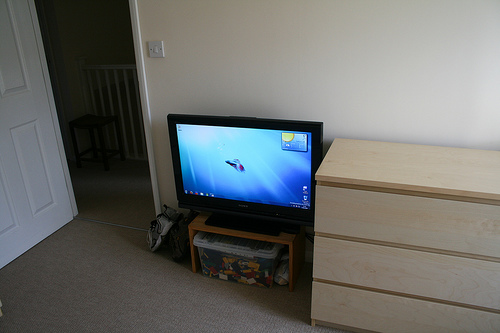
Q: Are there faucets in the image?
A: No, there are no faucets.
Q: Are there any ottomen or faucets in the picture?
A: No, there are no faucets or ottomen.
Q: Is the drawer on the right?
A: Yes, the drawer is on the right of the image.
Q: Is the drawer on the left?
A: No, the drawer is on the right of the image.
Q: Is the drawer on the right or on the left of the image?
A: The drawer is on the right of the image.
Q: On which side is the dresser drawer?
A: The drawer is on the right of the image.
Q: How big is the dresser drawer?
A: The drawer is large.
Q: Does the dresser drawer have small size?
A: No, the drawer is large.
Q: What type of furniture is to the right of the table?
A: The piece of furniture is a drawer.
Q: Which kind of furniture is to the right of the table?
A: The piece of furniture is a drawer.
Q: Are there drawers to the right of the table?
A: Yes, there is a drawer to the right of the table.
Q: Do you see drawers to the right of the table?
A: Yes, there is a drawer to the right of the table.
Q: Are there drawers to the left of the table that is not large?
A: No, the drawer is to the right of the table.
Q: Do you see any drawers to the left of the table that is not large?
A: No, the drawer is to the right of the table.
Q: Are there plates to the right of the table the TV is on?
A: No, there is a drawer to the right of the table.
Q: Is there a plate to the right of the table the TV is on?
A: No, there is a drawer to the right of the table.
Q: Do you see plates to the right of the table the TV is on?
A: No, there is a drawer to the right of the table.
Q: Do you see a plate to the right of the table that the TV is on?
A: No, there is a drawer to the right of the table.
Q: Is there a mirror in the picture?
A: No, there are no mirrors.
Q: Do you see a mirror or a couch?
A: No, there are no mirrors or couches.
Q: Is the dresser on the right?
A: Yes, the dresser is on the right of the image.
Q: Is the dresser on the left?
A: No, the dresser is on the right of the image.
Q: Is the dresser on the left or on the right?
A: The dresser is on the right of the image.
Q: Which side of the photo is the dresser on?
A: The dresser is on the right of the image.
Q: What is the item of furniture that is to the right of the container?
A: The piece of furniture is a dresser.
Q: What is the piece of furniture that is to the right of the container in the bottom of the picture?
A: The piece of furniture is a dresser.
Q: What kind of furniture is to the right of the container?
A: The piece of furniture is a dresser.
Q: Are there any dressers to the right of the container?
A: Yes, there is a dresser to the right of the container.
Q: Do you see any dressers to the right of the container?
A: Yes, there is a dresser to the right of the container.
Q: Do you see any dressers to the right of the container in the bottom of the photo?
A: Yes, there is a dresser to the right of the container.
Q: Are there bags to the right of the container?
A: No, there is a dresser to the right of the container.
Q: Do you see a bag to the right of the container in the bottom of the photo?
A: No, there is a dresser to the right of the container.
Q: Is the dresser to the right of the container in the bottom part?
A: Yes, the dresser is to the right of the container.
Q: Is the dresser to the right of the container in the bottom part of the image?
A: Yes, the dresser is to the right of the container.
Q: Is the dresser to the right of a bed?
A: No, the dresser is to the right of the container.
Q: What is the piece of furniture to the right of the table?
A: The piece of furniture is a dresser.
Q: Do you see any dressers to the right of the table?
A: Yes, there is a dresser to the right of the table.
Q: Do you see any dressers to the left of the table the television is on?
A: No, the dresser is to the right of the table.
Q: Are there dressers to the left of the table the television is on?
A: No, the dresser is to the right of the table.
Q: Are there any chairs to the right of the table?
A: No, there is a dresser to the right of the table.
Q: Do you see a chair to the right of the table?
A: No, there is a dresser to the right of the table.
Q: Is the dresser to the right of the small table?
A: Yes, the dresser is to the right of the table.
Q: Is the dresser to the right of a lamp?
A: No, the dresser is to the right of the table.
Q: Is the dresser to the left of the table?
A: No, the dresser is to the right of the table.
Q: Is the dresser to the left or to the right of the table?
A: The dresser is to the right of the table.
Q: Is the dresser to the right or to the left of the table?
A: The dresser is to the right of the table.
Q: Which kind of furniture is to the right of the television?
A: The piece of furniture is a dresser.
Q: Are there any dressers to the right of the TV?
A: Yes, there is a dresser to the right of the TV.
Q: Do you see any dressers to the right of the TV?
A: Yes, there is a dresser to the right of the TV.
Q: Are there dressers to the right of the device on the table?
A: Yes, there is a dresser to the right of the TV.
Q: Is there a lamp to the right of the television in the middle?
A: No, there is a dresser to the right of the TV.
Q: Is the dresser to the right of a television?
A: Yes, the dresser is to the right of a television.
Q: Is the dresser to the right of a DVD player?
A: No, the dresser is to the right of a television.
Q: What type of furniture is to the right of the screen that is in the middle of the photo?
A: The piece of furniture is a dresser.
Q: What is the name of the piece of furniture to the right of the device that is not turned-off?
A: The piece of furniture is a dresser.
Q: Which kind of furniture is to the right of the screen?
A: The piece of furniture is a dresser.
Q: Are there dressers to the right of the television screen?
A: Yes, there is a dresser to the right of the screen.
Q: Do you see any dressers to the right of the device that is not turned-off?
A: Yes, there is a dresser to the right of the screen.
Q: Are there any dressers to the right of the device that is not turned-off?
A: Yes, there is a dresser to the right of the screen.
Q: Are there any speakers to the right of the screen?
A: No, there is a dresser to the right of the screen.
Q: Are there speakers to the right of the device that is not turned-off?
A: No, there is a dresser to the right of the screen.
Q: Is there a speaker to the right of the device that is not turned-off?
A: No, there is a dresser to the right of the screen.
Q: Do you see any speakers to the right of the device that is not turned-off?
A: No, there is a dresser to the right of the screen.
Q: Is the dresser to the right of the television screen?
A: Yes, the dresser is to the right of the screen.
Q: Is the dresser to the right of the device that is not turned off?
A: Yes, the dresser is to the right of the screen.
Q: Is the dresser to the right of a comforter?
A: No, the dresser is to the right of the screen.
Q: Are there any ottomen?
A: No, there are no ottomen.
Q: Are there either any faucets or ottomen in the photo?
A: No, there are no ottomen or faucets.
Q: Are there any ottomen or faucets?
A: No, there are no ottomen or faucets.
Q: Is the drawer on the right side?
A: Yes, the drawer is on the right of the image.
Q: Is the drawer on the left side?
A: No, the drawer is on the right of the image.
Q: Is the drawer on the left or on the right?
A: The drawer is on the right of the image.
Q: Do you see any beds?
A: No, there are no beds.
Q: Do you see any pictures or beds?
A: No, there are no beds or pictures.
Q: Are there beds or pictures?
A: No, there are no beds or pictures.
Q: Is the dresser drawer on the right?
A: Yes, the drawer is on the right of the image.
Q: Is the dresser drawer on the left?
A: No, the drawer is on the right of the image.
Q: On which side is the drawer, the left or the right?
A: The drawer is on the right of the image.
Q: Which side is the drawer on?
A: The drawer is on the right of the image.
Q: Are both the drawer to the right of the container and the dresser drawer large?
A: Yes, both the drawer and the drawer are large.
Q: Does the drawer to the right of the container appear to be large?
A: Yes, the drawer is large.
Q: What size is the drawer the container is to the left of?
A: The drawer is large.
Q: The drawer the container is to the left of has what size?
A: The drawer is large.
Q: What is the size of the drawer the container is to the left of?
A: The drawer is large.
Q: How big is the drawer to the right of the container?
A: The drawer is large.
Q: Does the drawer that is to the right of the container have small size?
A: No, the drawer is large.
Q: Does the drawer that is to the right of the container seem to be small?
A: No, the drawer is large.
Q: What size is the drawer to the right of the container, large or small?
A: The drawer is large.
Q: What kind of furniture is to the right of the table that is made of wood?
A: The piece of furniture is a drawer.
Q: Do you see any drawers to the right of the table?
A: Yes, there is a drawer to the right of the table.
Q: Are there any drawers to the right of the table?
A: Yes, there is a drawer to the right of the table.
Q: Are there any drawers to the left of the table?
A: No, the drawer is to the right of the table.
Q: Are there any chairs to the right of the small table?
A: No, there is a drawer to the right of the table.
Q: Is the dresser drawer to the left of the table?
A: No, the drawer is to the right of the table.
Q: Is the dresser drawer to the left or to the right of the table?
A: The drawer is to the right of the table.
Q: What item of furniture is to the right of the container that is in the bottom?
A: The piece of furniture is a drawer.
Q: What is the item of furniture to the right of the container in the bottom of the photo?
A: The piece of furniture is a drawer.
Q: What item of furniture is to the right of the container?
A: The piece of furniture is a drawer.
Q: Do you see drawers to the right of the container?
A: Yes, there is a drawer to the right of the container.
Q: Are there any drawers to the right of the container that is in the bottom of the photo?
A: Yes, there is a drawer to the right of the container.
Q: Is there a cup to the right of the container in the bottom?
A: No, there is a drawer to the right of the container.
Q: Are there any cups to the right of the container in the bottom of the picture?
A: No, there is a drawer to the right of the container.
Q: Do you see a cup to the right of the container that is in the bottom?
A: No, there is a drawer to the right of the container.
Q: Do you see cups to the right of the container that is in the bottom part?
A: No, there is a drawer to the right of the container.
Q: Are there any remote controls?
A: No, there are no remote controls.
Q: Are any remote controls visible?
A: No, there are no remote controls.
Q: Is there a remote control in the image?
A: No, there are no remote controls.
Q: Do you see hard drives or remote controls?
A: No, there are no remote controls or hard drives.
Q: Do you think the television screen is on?
A: Yes, the screen is on.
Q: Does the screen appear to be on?
A: Yes, the screen is on.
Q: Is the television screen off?
A: No, the screen is on.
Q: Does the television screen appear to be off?
A: No, the screen is on.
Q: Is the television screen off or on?
A: The screen is on.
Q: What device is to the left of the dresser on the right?
A: The device is a screen.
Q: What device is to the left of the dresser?
A: The device is a screen.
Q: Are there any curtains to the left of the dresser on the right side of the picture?
A: No, there is a screen to the left of the dresser.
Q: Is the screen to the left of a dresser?
A: Yes, the screen is to the left of a dresser.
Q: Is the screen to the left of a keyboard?
A: No, the screen is to the left of a dresser.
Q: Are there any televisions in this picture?
A: Yes, there is a television.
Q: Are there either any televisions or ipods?
A: Yes, there is a television.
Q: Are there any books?
A: No, there are no books.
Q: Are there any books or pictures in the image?
A: No, there are no books or pictures.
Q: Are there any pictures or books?
A: No, there are no books or pictures.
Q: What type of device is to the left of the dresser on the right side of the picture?
A: The device is a television.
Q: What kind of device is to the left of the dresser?
A: The device is a television.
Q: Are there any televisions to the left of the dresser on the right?
A: Yes, there is a television to the left of the dresser.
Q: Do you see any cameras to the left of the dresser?
A: No, there is a television to the left of the dresser.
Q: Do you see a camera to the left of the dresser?
A: No, there is a television to the left of the dresser.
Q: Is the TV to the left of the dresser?
A: Yes, the TV is to the left of the dresser.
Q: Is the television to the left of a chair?
A: No, the television is to the left of the dresser.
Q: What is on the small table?
A: The TV is on the table.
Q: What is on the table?
A: The TV is on the table.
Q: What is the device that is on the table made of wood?
A: The device is a television.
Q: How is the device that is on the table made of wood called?
A: The device is a television.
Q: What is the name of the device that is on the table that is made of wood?
A: The device is a television.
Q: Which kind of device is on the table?
A: The device is a television.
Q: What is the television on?
A: The television is on the table.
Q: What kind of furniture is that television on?
A: The television is on the table.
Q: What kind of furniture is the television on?
A: The television is on the table.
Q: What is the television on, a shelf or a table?
A: The television is on a table.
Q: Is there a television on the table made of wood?
A: Yes, there is a television on the table.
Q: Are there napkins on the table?
A: No, there is a television on the table.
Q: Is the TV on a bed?
A: No, the TV is on the table.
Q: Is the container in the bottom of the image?
A: Yes, the container is in the bottom of the image.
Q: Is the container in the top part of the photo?
A: No, the container is in the bottom of the image.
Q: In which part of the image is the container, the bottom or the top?
A: The container is in the bottom of the image.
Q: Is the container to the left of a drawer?
A: Yes, the container is to the left of a drawer.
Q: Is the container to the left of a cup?
A: No, the container is to the left of a drawer.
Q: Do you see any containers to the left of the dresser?
A: Yes, there is a container to the left of the dresser.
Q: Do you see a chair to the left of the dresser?
A: No, there is a container to the left of the dresser.